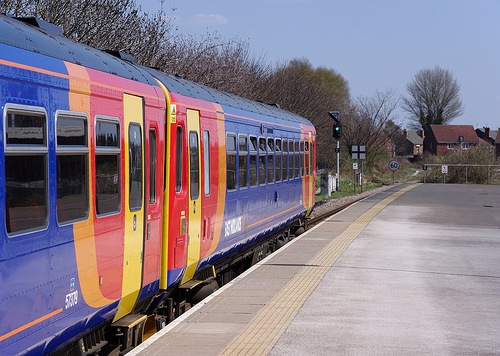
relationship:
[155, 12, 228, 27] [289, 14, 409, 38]
cloud in sky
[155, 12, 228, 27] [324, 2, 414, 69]
cloud in sky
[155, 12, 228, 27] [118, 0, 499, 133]
cloud in blue sky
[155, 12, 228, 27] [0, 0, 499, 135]
cloud in blue sky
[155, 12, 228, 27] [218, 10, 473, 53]
cloud in sky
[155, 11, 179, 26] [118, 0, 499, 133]
cloud in blue sky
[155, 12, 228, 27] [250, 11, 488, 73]
cloud in sky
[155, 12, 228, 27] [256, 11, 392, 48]
cloud in sky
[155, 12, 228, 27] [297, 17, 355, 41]
cloud in sky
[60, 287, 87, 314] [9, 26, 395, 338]
number of train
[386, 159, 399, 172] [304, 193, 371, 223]
sign beside tracks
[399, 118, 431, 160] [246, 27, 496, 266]
house in background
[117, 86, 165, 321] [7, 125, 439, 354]
door to railroad cart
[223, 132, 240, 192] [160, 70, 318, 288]
window to railroad cart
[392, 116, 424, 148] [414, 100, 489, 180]
chimney on top of house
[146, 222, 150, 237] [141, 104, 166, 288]
handle to door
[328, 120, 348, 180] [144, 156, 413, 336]
power box by railroad track